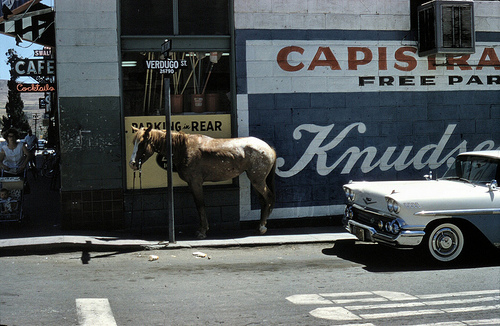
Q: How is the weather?
A: Clear.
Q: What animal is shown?
A: A horse.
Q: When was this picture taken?
A: Daytime.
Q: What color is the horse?
A: Brown.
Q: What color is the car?
A: White.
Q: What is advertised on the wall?
A: Capistra.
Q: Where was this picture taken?
A: A street.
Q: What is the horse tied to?
A: A pole.